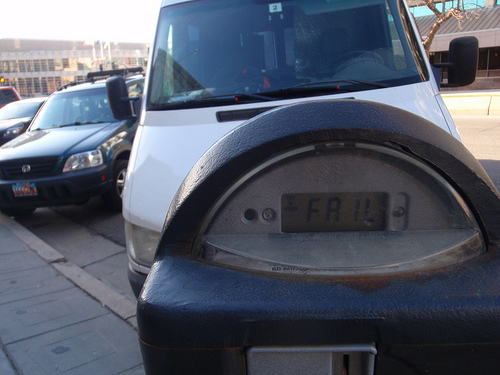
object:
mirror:
[448, 36, 480, 88]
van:
[119, 0, 478, 303]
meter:
[134, 95, 500, 375]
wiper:
[197, 93, 278, 103]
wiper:
[280, 79, 388, 93]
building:
[0, 38, 157, 100]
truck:
[0, 75, 146, 220]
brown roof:
[412, 5, 500, 38]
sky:
[0, 0, 173, 52]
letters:
[307, 195, 378, 223]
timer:
[280, 192, 388, 233]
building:
[403, 0, 500, 93]